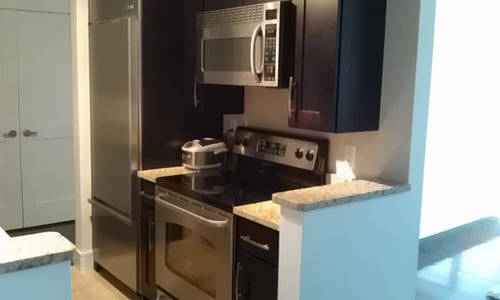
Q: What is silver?
A: Microwave.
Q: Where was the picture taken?
A: In a kitchen.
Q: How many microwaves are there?
A: One.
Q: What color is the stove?
A: Black.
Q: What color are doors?
A: White.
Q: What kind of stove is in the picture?
A: Electric.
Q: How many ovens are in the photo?
A: One.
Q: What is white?
A: The wall.